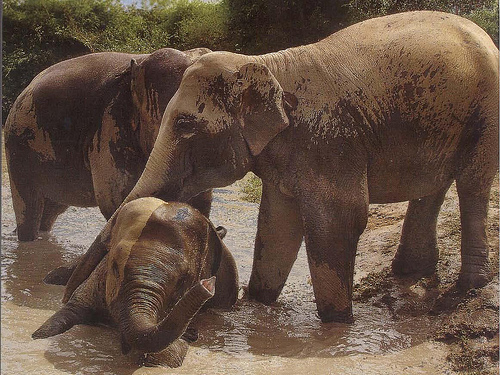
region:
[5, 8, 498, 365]
elephants taking a bath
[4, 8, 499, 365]
three elephants in shot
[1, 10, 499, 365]
elephants are brown and grey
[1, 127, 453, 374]
water is brown and muddy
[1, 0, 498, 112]
tree leaves are green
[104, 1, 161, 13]
sky is blue behind trees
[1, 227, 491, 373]
elephants cast shadow on river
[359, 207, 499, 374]
mud has several tracks in it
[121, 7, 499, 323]
elephant has two legs on land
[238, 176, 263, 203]
patch of green grass on ground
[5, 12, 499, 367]
the three elephants playing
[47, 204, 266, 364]
the baby elephant in the water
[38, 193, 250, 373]
the baby elephant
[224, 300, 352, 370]
the dirty water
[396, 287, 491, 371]
the mud on the ground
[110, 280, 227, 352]
the baby trunk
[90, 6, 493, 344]
the big elephant facing the left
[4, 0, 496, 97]
the trees behind the elephants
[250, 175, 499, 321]
the four legs on the elephant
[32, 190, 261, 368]
the baby elephant lying down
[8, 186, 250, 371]
elephant in a mud hole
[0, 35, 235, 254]
elephant in a mud hole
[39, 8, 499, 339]
elephant in a mud hole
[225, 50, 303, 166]
ear of an elephant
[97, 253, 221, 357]
trunk of an elephant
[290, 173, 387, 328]
leg of an elephant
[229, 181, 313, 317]
leg of an elephant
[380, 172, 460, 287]
leg of an elephant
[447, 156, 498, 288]
leg of an elephant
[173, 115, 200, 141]
eye of an elephant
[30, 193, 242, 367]
The elephant lying in th water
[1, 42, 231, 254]
The standing elephant on the left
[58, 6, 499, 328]
The standing elephant on the right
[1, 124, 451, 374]
The water the elephants are in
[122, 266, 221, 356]
The trunk of the elephant lying down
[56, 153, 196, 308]
The trunk of the elephant on the right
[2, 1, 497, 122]
The trees behind the elephants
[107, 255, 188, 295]
The eyes of the elephant lying down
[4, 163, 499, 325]
The legs of the standing elephants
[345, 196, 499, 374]
The muddy riverbank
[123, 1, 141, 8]
this is the sky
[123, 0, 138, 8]
the sky is blue in color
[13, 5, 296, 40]
these are some trees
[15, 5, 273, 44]
the trees are short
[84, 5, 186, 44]
the trees have leaves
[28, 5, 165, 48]
the leaves are green in color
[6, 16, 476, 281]
these are three elephants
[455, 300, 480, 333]
this is some mud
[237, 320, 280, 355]
this is muddy water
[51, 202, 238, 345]
the elephant is in the water